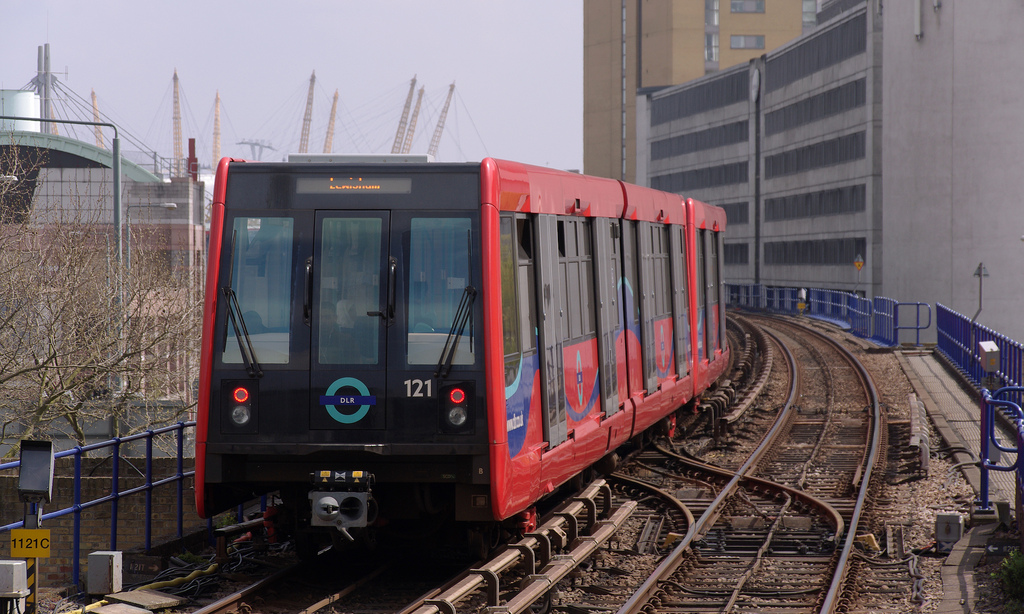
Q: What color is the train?
A: Red and black.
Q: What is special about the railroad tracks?
A: They criss- cross.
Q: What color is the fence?
A: Blue.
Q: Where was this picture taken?
A: On a railway.